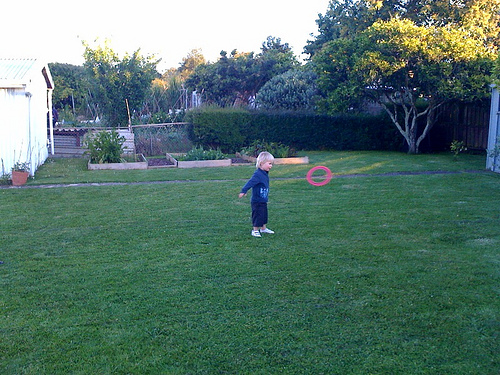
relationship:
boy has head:
[237, 148, 279, 241] [253, 149, 277, 174]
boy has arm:
[237, 148, 279, 241] [239, 167, 262, 198]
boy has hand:
[237, 148, 279, 241] [239, 187, 251, 201]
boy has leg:
[237, 148, 279, 241] [246, 199, 268, 241]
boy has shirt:
[237, 148, 279, 241] [243, 167, 270, 204]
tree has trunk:
[315, 16, 499, 154] [377, 91, 451, 153]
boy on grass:
[237, 148, 279, 241] [1, 148, 499, 373]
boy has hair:
[237, 148, 279, 241] [257, 150, 275, 168]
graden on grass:
[86, 116, 311, 167] [1, 148, 499, 373]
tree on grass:
[315, 16, 499, 154] [1, 148, 499, 373]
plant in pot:
[10, 156, 32, 174] [14, 167, 31, 185]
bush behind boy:
[188, 105, 419, 153] [237, 148, 279, 241]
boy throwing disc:
[237, 148, 279, 241] [303, 162, 331, 187]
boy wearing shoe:
[237, 148, 279, 241] [250, 225, 263, 240]